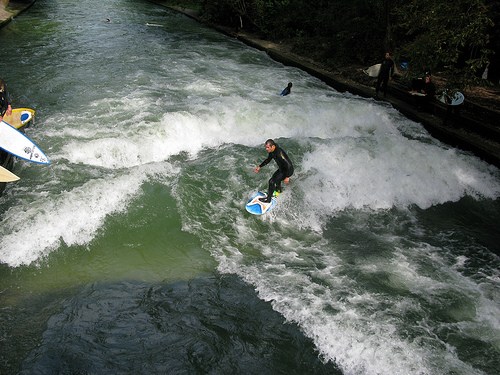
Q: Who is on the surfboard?
A: A man.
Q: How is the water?
A: Rough.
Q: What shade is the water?
A: Green.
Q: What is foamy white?
A: The waves.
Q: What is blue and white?
A: Surfboards.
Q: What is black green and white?
A: Water.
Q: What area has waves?
A: The water.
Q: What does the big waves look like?
A: White.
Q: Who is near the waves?
A: The surfer.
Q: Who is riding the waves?
A: The surfer.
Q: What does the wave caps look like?
A: White.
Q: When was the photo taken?
A: Daytime.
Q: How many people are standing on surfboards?
A: One.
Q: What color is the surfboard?
A: Yellow, blue, and white.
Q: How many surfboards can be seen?
A: Five.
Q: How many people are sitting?
A: One.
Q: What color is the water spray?
A: White.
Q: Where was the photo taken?
A: In the river.